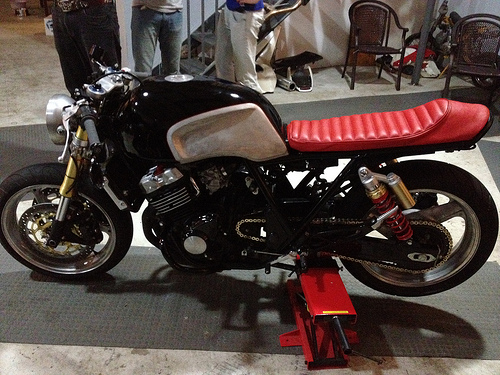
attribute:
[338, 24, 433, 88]
chair — steel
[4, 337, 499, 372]
pavement — grey 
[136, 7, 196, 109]
jean — blue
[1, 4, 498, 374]
pavement — grey 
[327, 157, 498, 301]
tire — rear, motorcycle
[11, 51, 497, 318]
bike — red 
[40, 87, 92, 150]
lamp — motorcycle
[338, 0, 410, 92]
chair — steel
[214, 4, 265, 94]
pants — beige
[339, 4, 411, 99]
chair — black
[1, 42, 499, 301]
motorcycle — red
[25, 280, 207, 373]
pavement — grey 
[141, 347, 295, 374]
pavement — grey 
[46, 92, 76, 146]
headlight — motorcycle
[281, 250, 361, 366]
motorcycle ramp — red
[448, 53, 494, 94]
chair — black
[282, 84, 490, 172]
seat — red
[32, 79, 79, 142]
light — silver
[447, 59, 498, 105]
chair — brown